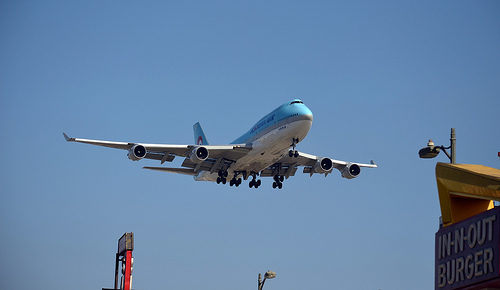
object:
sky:
[0, 0, 500, 290]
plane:
[60, 97, 376, 190]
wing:
[61, 133, 190, 156]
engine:
[128, 144, 149, 160]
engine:
[190, 146, 213, 163]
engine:
[311, 154, 333, 172]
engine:
[340, 160, 362, 179]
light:
[415, 126, 458, 160]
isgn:
[116, 232, 137, 289]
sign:
[435, 161, 496, 288]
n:
[453, 227, 465, 253]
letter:
[463, 220, 477, 246]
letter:
[478, 216, 489, 247]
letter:
[485, 210, 499, 230]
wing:
[289, 153, 377, 179]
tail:
[192, 123, 210, 146]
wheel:
[215, 169, 226, 184]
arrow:
[435, 157, 500, 224]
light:
[255, 270, 273, 287]